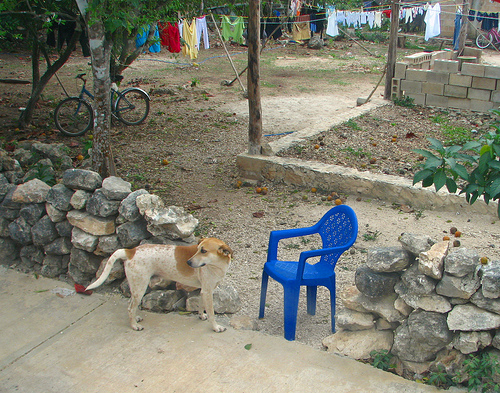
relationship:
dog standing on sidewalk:
[87, 236, 234, 335] [1, 259, 476, 391]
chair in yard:
[258, 201, 360, 341] [2, 29, 497, 389]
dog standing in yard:
[87, 236, 234, 335] [1, 27, 460, 323]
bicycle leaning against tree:
[48, 68, 155, 139] [66, 1, 220, 123]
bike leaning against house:
[475, 25, 499, 47] [416, 0, 498, 49]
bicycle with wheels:
[48, 68, 155, 139] [52, 88, 152, 137]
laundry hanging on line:
[325, 11, 388, 30] [178, 14, 421, 30]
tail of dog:
[83, 247, 124, 290] [78, 233, 235, 338]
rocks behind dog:
[53, 151, 243, 277] [93, 215, 283, 324]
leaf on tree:
[411, 144, 436, 160] [409, 104, 499, 210]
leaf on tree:
[409, 168, 431, 185] [409, 104, 499, 210]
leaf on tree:
[431, 168, 447, 191] [409, 104, 499, 210]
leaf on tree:
[458, 138, 480, 150] [409, 104, 499, 210]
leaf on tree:
[441, 152, 456, 170] [409, 104, 499, 210]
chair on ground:
[258, 201, 360, 341] [30, 40, 487, 328]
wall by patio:
[394, 64, 497, 124] [256, 66, 498, 202]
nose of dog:
[182, 257, 192, 268] [101, 234, 234, 325]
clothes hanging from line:
[141, 17, 243, 52] [201, 6, 329, 35]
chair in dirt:
[246, 193, 367, 362] [216, 218, 378, 367]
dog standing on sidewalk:
[91, 224, 273, 335] [3, 296, 213, 390]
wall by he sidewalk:
[320, 231, 499, 386] [1, 259, 476, 391]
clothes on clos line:
[329, 14, 337, 36] [262, 17, 325, 22]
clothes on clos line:
[423, 4, 438, 38] [262, 17, 325, 22]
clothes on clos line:
[182, 21, 199, 56] [262, 17, 325, 22]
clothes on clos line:
[195, 17, 210, 48] [262, 17, 325, 22]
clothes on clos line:
[220, 17, 242, 42] [262, 17, 325, 22]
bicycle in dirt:
[48, 68, 155, 139] [3, 38, 497, 353]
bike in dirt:
[473, 15, 498, 50] [3, 38, 497, 353]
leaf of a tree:
[413, 169, 435, 186] [398, 91, 464, 233]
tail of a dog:
[83, 247, 124, 290] [83, 237, 233, 332]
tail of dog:
[83, 247, 124, 290] [81, 229, 231, 335]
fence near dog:
[323, 231, 498, 391] [83, 237, 233, 332]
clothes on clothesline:
[133, 2, 469, 64] [135, 2, 484, 57]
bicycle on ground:
[48, 68, 155, 139] [4, 37, 498, 272]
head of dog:
[184, 228, 234, 277] [81, 229, 231, 335]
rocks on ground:
[207, 205, 296, 235] [160, 140, 241, 210]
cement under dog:
[2, 265, 443, 391] [81, 229, 231, 335]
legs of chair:
[258, 278, 343, 346] [251, 203, 362, 331]